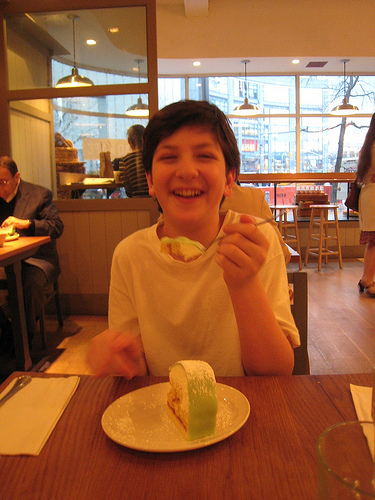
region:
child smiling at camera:
[134, 98, 248, 226]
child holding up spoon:
[131, 96, 293, 269]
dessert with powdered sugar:
[95, 354, 254, 455]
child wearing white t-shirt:
[98, 99, 302, 377]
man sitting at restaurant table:
[4, 151, 74, 364]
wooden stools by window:
[262, 74, 349, 272]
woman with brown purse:
[340, 116, 373, 298]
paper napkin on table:
[0, 360, 81, 467]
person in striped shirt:
[109, 125, 157, 201]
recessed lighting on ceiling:
[73, 22, 312, 86]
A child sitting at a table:
[108, 100, 310, 365]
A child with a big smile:
[137, 99, 242, 213]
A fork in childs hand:
[150, 226, 289, 279]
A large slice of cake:
[158, 347, 213, 438]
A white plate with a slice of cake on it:
[106, 377, 228, 457]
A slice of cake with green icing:
[173, 360, 213, 432]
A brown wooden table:
[265, 380, 314, 472]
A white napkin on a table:
[25, 382, 59, 442]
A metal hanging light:
[238, 64, 287, 122]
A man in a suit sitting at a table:
[4, 153, 64, 245]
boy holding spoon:
[85, 98, 300, 396]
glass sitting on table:
[312, 414, 373, 498]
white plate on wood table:
[97, 366, 247, 453]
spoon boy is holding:
[194, 204, 294, 258]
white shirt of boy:
[103, 221, 301, 372]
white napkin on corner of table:
[1, 371, 85, 456]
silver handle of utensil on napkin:
[1, 371, 30, 405]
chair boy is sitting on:
[284, 262, 321, 373]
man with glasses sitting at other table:
[3, 151, 60, 348]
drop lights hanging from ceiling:
[53, 13, 366, 119]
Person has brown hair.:
[154, 97, 236, 146]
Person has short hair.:
[154, 91, 222, 141]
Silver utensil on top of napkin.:
[6, 371, 31, 422]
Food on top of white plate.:
[115, 372, 236, 479]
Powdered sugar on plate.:
[111, 397, 176, 446]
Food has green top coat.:
[163, 343, 226, 443]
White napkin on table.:
[30, 392, 82, 459]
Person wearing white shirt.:
[159, 302, 228, 332]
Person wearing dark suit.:
[15, 189, 69, 264]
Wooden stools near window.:
[272, 196, 340, 262]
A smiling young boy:
[93, 102, 301, 372]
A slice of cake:
[100, 360, 248, 454]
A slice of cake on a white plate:
[97, 361, 249, 446]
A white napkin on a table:
[0, 374, 83, 455]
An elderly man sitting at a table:
[2, 158, 57, 336]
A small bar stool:
[307, 203, 341, 269]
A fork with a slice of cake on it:
[156, 212, 285, 260]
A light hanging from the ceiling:
[59, 26, 97, 89]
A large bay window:
[52, 63, 371, 221]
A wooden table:
[3, 370, 372, 498]